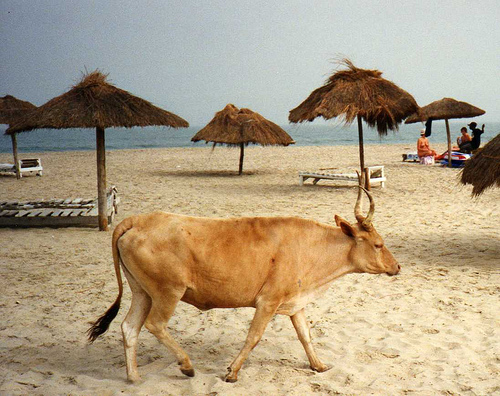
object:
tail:
[82, 217, 133, 346]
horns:
[355, 170, 376, 232]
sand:
[192, 327, 222, 362]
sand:
[180, 159, 340, 203]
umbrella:
[2, 64, 188, 232]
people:
[417, 128, 438, 158]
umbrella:
[404, 97, 485, 168]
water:
[37, 129, 85, 149]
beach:
[0, 139, 500, 396]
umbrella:
[286, 51, 421, 191]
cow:
[82, 169, 402, 386]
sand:
[412, 300, 500, 396]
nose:
[392, 262, 401, 272]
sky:
[119, 27, 339, 83]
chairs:
[0, 184, 121, 229]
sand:
[16, 355, 101, 396]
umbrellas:
[190, 102, 296, 176]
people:
[459, 122, 485, 154]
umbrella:
[440, 133, 499, 206]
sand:
[425, 193, 489, 214]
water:
[164, 124, 193, 143]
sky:
[425, 42, 499, 74]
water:
[295, 120, 322, 142]